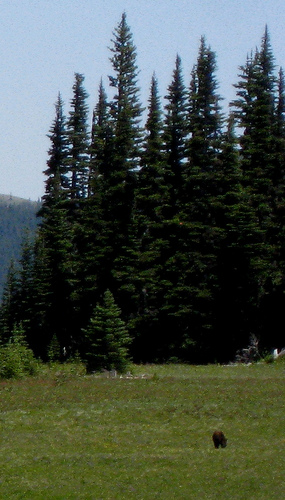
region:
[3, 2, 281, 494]
A large clear forest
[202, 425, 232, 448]
A large brown bear walks towards the forest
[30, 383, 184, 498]
Thick green grass is on the field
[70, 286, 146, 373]
A tall green tree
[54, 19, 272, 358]
A thick forest filled with green trees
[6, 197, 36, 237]
A tree covered hilly area in the background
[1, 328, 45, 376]
A small green bush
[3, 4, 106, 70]
A clear blue sky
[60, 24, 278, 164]
The top of the forest.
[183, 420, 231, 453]
A small brown bear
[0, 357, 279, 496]
a bear in a green field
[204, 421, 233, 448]
bear is color brown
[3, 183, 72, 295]
a mountain behind the trees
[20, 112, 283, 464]
trees in front a green field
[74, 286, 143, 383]
a small green pine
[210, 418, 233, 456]
head of bear is down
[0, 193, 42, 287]
trees in the mountain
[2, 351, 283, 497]
a field covered with green grass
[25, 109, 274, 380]
green pines are very tall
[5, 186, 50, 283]
there are trees in the mountain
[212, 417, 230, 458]
brown bear walking in a field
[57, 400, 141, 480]
green grass in a field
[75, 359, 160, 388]
rocks at the bottom of a tree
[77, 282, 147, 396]
evergreen tree in a field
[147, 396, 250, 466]
one tiny bear in a field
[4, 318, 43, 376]
group of small evergreen trees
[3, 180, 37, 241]
tree covered mountain in the distance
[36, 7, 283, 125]
tops of very tall evergreen trees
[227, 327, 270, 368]
bush without leaves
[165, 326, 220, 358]
shadows from the bottom of tall trees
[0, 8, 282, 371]
Tall cone shaped trees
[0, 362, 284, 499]
Open area covered with green grass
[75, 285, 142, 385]
Short cone shaped tree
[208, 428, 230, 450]
Black colored animal in the grass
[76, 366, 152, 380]
White objects standing in the grass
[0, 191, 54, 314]
Tall hill standing in the background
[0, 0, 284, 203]
Expanse of open blue sky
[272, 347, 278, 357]
White painted object standing on the ground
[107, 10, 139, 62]
Tip of a tall tree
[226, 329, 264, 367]
Short greying tree laying on the side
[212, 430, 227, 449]
dark brown animal in foreground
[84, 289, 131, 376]
small green evergreen tree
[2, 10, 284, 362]
talldark green trees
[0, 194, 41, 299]
mountain with green trees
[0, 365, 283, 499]
green and yellow grass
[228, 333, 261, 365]
light colored bush beyond grass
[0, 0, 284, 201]
clear blue and grey sky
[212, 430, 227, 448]
dark animal eating grass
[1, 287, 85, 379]
medium and small green bushes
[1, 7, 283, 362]
tall dark green evergreen trees